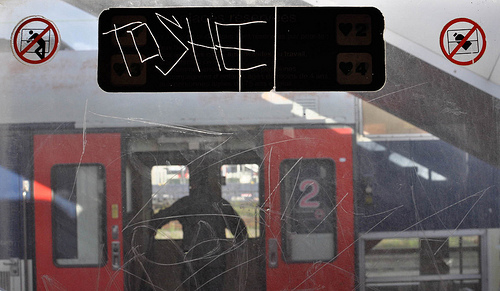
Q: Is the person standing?
A: Yes, the person is standing.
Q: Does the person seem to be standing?
A: Yes, the person is standing.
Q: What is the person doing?
A: The person is standing.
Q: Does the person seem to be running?
A: No, the person is standing.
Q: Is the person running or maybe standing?
A: The person is standing.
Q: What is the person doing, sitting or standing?
A: The person is standing.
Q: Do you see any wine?
A: No, there is no wine.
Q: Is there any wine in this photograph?
A: No, there is no wine.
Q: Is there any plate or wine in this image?
A: No, there are no wine or plates.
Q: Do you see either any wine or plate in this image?
A: No, there are no wine or plates.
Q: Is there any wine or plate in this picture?
A: No, there are no wine or plates.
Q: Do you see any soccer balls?
A: No, there are no soccer balls.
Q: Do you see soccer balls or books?
A: No, there are no soccer balls or books.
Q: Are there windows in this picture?
A: Yes, there is a window.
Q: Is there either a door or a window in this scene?
A: Yes, there is a window.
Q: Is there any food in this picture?
A: No, there is no food.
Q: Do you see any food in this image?
A: No, there is no food.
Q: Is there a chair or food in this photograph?
A: No, there are no food or chairs.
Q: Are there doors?
A: Yes, there is a door.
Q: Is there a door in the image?
A: Yes, there is a door.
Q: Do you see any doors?
A: Yes, there is a door.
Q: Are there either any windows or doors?
A: Yes, there is a door.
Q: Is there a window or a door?
A: Yes, there is a door.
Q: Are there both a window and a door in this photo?
A: Yes, there are both a door and a window.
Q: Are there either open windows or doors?
A: Yes, there is an open door.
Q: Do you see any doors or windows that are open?
A: Yes, the door is open.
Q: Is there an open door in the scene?
A: Yes, there is an open door.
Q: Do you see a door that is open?
A: Yes, there is a door that is open.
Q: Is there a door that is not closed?
A: Yes, there is a open door.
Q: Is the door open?
A: Yes, the door is open.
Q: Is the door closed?
A: No, the door is open.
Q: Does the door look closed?
A: No, the door is open.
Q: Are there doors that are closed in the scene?
A: No, there is a door but it is open.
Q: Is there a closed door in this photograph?
A: No, there is a door but it is open.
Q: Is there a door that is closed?
A: No, there is a door but it is open.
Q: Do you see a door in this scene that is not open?
A: No, there is a door but it is open.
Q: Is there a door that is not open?
A: No, there is a door but it is open.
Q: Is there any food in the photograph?
A: No, there is no food.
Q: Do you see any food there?
A: No, there is no food.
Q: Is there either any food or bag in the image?
A: No, there are no food or bags.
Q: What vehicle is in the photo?
A: The vehicle is a train car.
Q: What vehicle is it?
A: The vehicle is a train car.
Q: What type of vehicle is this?
A: This is a train car.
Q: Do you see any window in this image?
A: Yes, there is a window.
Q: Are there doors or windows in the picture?
A: Yes, there is a window.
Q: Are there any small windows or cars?
A: Yes, there is a small window.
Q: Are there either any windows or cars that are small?
A: Yes, the window is small.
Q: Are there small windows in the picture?
A: Yes, there is a small window.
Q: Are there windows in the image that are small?
A: Yes, there is a small window.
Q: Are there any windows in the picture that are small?
A: Yes, there is a window that is small.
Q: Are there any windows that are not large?
A: Yes, there is a small window.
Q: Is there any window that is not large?
A: Yes, there is a small window.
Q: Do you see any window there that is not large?
A: Yes, there is a small window.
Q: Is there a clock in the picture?
A: No, there are no clocks.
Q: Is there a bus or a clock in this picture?
A: No, there are no clocks or buses.